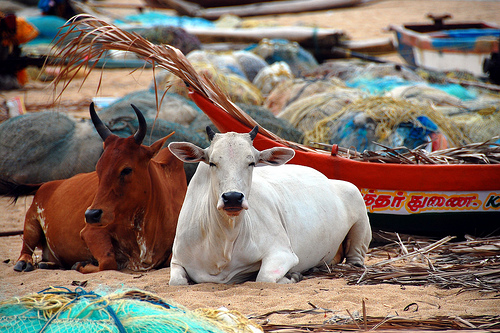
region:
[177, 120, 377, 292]
white bull laying down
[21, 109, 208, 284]
brown bull laying down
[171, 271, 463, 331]
sand with sticks in it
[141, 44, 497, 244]
red boat sitting in the sand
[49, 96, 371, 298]
bulls laying in the sand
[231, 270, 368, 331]
the sand is brown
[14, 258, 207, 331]
blue decoration in the sand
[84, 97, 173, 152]
bull has black horns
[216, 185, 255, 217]
bull has black nose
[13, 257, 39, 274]
bull has black hooves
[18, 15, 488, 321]
cows amid seaside clutter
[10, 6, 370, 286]
long reeds curving over cows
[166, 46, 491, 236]
pointy boat filled with nets and buoys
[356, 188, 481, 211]
red lettering outlined in orange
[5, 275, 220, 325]
blue circle of buoys covered under netting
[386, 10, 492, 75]
empty blue and white boat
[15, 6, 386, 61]
gray poles and blue fabric in back of boat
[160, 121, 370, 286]
white cow with short black horns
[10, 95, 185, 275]
brown cow with dark curved horns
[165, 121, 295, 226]
face looking directly ahead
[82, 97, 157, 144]
long black horns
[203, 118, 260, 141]
short black horns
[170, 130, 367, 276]
white cow on the ground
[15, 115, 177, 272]
brown cow with black hooves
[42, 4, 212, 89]
streamers out of a boat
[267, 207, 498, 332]
pile of sticks on the ground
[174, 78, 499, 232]
red black and white boat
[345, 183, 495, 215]
writing on a boat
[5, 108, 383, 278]
two cows on the ground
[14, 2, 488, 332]
fabric and garbage on the ground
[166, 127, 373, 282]
a white cow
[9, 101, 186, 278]
a brown cow with white spots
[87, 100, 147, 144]
a pair of black horns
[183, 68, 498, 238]
a black and red boat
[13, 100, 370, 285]
two cows laying by each other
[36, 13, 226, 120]
a dead brown palm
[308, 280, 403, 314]
a patch of sand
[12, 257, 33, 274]
a black cow hoof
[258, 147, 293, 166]
a cows left ear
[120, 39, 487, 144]
a lot of bags wrapped in fishing net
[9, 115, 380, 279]
two cows laying on the beach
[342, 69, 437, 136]
bags filled with fishing nets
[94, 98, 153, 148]
tall black cow horns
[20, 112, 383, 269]
one brown cow and one white cow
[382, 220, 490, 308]
twigs on the sand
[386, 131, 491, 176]
twigs in the canoe boat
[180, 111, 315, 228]
cow looking directly at camera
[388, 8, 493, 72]
small row boat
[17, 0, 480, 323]
boats and fishing equpiment on the beach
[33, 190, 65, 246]
white spots on brown cow